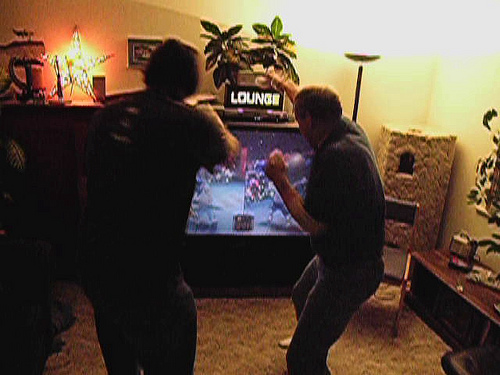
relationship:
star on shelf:
[41, 21, 115, 103] [4, 92, 121, 120]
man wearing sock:
[272, 81, 383, 362] [274, 335, 295, 349]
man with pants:
[76, 38, 243, 373] [91, 271, 198, 371]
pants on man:
[91, 271, 198, 371] [76, 38, 243, 373]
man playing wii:
[76, 54, 244, 373] [55, 102, 108, 160]